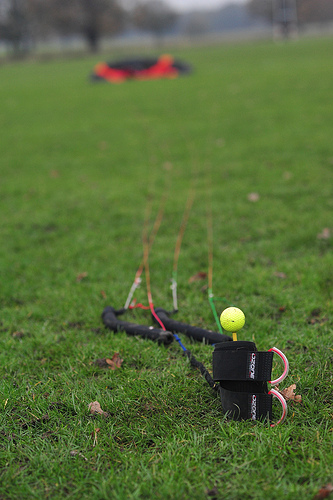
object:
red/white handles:
[268, 346, 291, 386]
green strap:
[208, 289, 223, 333]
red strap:
[144, 259, 166, 331]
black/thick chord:
[152, 309, 234, 343]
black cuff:
[212, 340, 274, 384]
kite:
[86, 54, 196, 83]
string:
[206, 194, 214, 288]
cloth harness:
[219, 387, 273, 423]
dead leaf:
[105, 351, 124, 371]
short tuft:
[149, 407, 168, 432]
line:
[173, 334, 186, 351]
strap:
[102, 306, 173, 344]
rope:
[124, 262, 144, 309]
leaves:
[87, 401, 109, 419]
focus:
[107, 54, 158, 70]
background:
[0, 0, 332, 248]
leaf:
[273, 383, 301, 405]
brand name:
[248, 350, 256, 380]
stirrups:
[268, 387, 289, 426]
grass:
[2, 36, 333, 493]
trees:
[131, 2, 181, 50]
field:
[0, 38, 331, 498]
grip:
[268, 387, 289, 428]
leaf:
[188, 271, 207, 283]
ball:
[219, 305, 246, 332]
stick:
[232, 332, 237, 341]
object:
[126, 293, 168, 334]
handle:
[102, 302, 174, 345]